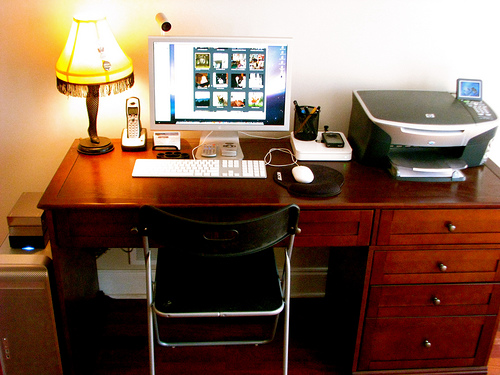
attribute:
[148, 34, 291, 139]
monitor — flat screen, on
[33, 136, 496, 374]
desk — dark, wooden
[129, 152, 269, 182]
keyboard — white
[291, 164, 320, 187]
mouse — white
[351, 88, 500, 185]
printer — black, silver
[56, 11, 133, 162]
lamp — small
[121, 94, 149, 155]
phone — wireless, silver, black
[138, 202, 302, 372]
chair — chrome, black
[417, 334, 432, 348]
knob — brushed nickel, silver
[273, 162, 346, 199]
mouse pad — black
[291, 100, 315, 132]
pen — black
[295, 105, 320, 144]
pencil holder — metal, mesh, black mesh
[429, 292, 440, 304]
knob — brushed nickel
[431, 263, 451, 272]
knob — brushed nickel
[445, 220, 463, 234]
knob — brushed nickel